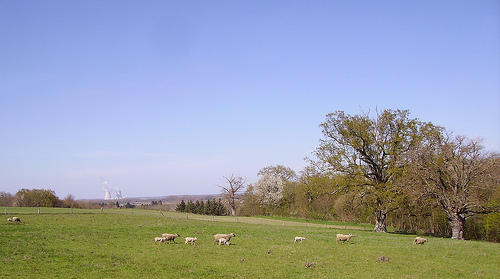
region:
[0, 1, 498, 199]
Blue sky with very little white clouds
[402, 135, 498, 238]
The fattest brown tree that is very wide and shorter than the others.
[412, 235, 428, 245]
Tan sheep between two large trees.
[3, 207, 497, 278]
A long green grass field with animals in it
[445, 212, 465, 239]
The fattest brown tree trunk.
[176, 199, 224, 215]
A row of 7 pine trees all the same size.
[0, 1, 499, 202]
A blue sky.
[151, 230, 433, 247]
a group of sheep in a field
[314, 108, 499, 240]
two trees in a field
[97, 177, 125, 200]
a white tower in the distance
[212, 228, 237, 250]
a mother and baby lamb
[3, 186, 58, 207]
a clump of tree to the left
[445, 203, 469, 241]
the wide trunk of a gray tree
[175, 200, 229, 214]
a line of dark green pine trees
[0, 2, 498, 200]
clear blue sky over a field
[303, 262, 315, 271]
a clump of dead grass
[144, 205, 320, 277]
animals in the field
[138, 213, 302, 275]
animals on the green grass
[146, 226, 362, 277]
animals walking on grass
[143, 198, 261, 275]
animals on green grass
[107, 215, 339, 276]
sheep are walking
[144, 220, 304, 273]
sheep walking on grass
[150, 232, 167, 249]
sheep in the grass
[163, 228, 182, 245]
sheep in the grass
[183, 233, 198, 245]
sheep in the grass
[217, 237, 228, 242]
sheep in the grass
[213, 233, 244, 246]
sheep in the grass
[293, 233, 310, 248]
sheep in the grass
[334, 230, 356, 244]
sheep in the grass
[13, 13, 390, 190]
a sky that is blue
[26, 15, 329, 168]
a sky that is clear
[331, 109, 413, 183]
green leaves on the tree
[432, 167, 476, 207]
bare branches on tree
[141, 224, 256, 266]
sheep walking in the pasture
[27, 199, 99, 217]
white posts in the field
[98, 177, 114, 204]
white tower in the far off distance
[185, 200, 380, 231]
cleared pathway on the side of grass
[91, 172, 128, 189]
smoke coming out of the building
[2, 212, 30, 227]
sheep laying on the grass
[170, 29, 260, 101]
the sky is clear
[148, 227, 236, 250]
lambs in the field.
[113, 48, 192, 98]
a clear blue sky